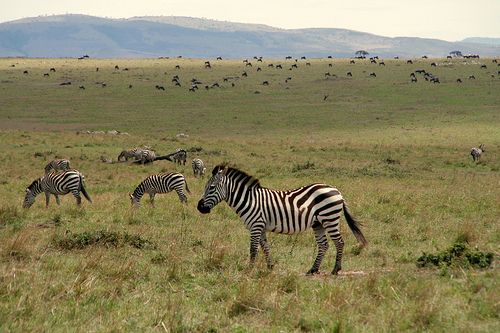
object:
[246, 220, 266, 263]
leg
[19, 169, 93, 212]
animals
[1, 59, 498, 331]
grass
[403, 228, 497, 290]
bush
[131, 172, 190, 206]
zebra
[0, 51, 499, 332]
field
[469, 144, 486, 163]
zebra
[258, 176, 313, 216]
stripes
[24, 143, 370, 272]
several zebra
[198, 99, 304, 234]
floor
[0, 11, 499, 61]
mountain range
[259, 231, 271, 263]
leg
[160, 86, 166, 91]
animals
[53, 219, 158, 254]
bush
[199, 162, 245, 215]
head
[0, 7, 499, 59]
hillside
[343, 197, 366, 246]
tail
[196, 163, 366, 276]
zebra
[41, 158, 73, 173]
zebra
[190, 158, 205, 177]
zebra